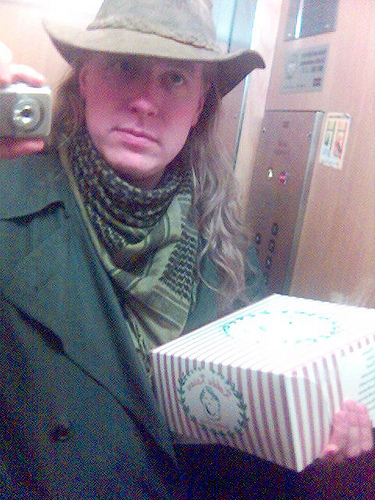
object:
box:
[149, 291, 375, 471]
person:
[200, 389, 217, 414]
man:
[2, 1, 370, 498]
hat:
[42, 0, 265, 79]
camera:
[1, 87, 53, 138]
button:
[277, 170, 288, 185]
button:
[271, 222, 277, 231]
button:
[267, 238, 276, 249]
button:
[50, 421, 71, 440]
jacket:
[1, 147, 310, 499]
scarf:
[55, 122, 205, 379]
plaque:
[274, 46, 333, 92]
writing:
[298, 48, 329, 74]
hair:
[41, 53, 250, 303]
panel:
[243, 105, 327, 301]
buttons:
[265, 256, 273, 268]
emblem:
[174, 366, 254, 439]